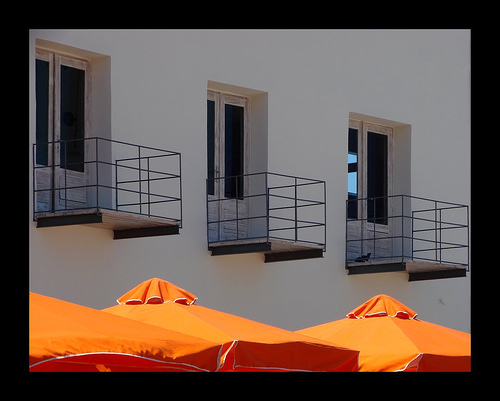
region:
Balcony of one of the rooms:
[30, 135, 183, 240]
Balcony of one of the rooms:
[205, 170, 325, 260]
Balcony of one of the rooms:
[340, 190, 465, 280]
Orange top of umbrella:
[301, 296, 469, 374]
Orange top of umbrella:
[100, 275, 357, 370]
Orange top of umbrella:
[27, 290, 218, 368]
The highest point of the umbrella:
[345, 285, 415, 317]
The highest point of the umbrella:
[116, 275, 196, 305]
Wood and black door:
[207, 87, 245, 235]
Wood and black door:
[349, 118, 396, 260]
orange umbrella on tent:
[100, 260, 216, 316]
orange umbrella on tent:
[347, 283, 421, 329]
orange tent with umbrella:
[317, 275, 475, 385]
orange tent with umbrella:
[102, 254, 347, 396]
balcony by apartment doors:
[337, 94, 464, 296]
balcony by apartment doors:
[199, 63, 332, 282]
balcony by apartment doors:
[31, 32, 204, 269]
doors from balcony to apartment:
[347, 114, 399, 261]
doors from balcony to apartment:
[200, 78, 260, 242]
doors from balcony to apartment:
[36, 37, 83, 213]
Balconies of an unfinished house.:
[30, 131, 465, 271]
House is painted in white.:
[30, 30, 465, 285]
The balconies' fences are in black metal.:
[30, 135, 470, 265]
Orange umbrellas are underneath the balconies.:
[25, 280, 466, 365]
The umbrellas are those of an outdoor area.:
[32, 277, 471, 369]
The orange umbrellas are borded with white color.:
[30, 275, 465, 365]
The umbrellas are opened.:
[30, 275, 465, 365]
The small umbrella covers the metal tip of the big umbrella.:
[115, 275, 195, 305]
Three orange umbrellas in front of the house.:
[30, 275, 465, 370]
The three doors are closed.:
[36, 41, 464, 276]